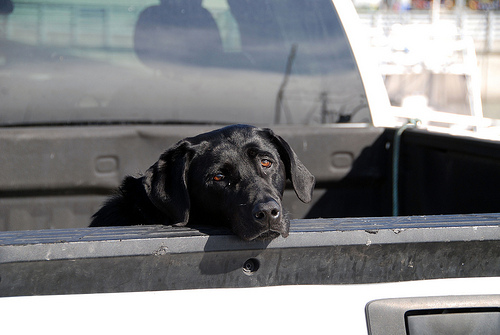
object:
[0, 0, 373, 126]
window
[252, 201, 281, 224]
nose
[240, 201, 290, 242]
muzzle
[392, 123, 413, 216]
rope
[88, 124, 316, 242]
dog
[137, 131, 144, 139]
dent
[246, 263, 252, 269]
screw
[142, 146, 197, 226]
ear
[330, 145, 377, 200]
ground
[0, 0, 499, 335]
pickup truck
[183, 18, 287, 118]
wall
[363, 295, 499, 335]
handle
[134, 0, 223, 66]
head rest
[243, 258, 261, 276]
key hole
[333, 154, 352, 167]
knob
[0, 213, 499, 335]
tailgate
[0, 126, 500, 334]
bed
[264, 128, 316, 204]
ear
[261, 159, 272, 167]
eye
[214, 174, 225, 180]
eye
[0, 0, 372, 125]
back window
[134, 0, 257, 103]
seat